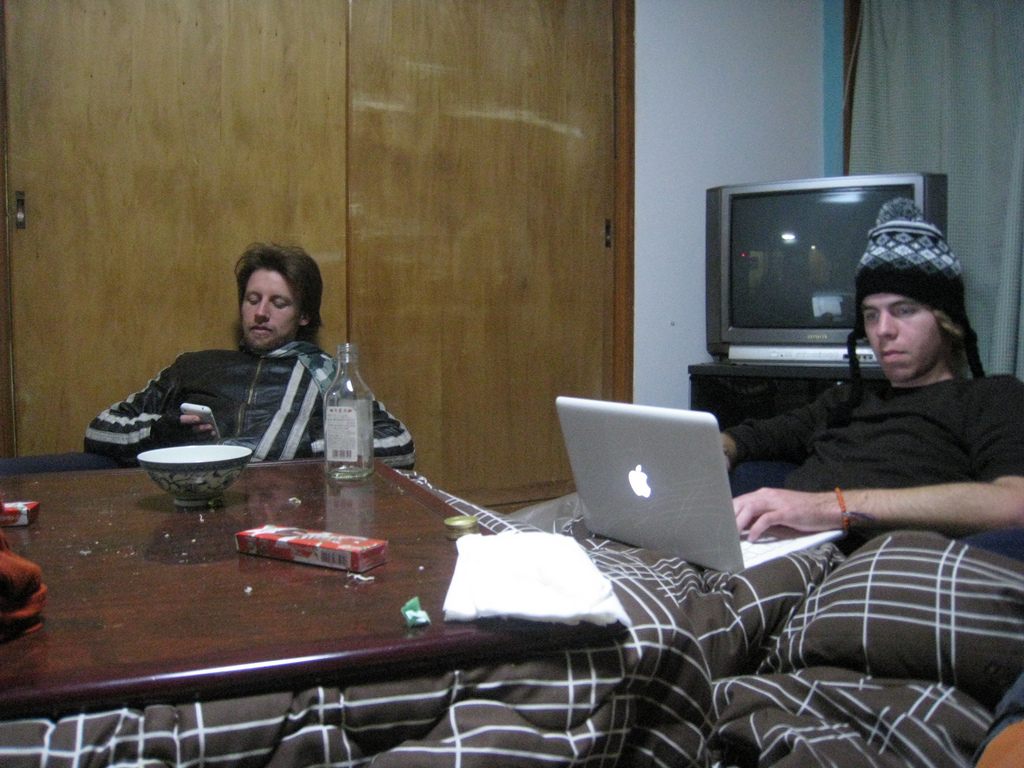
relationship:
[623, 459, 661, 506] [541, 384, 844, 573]
apple on computer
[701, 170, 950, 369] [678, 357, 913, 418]
television set on table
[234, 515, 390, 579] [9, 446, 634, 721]
cigarette box on table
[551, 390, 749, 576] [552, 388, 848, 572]
back lid on laptop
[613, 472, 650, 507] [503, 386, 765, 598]
back lid of laptop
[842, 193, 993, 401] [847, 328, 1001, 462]
bonnet hat on man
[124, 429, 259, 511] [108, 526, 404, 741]
bowl bowl on table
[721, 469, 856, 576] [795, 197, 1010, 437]
hand of man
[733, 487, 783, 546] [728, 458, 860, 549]
finger on hand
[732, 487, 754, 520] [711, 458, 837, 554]
finger on hand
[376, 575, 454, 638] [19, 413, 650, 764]
garbage on table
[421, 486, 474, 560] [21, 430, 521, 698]
garbage on wood table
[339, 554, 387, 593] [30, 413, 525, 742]
garbage on wood table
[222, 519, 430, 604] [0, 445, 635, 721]
garbage on table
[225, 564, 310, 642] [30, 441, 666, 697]
garbage on wood table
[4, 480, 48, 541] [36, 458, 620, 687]
garbage on wood table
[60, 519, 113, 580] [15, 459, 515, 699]
garbage on wood table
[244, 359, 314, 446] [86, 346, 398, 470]
stripes on a jacket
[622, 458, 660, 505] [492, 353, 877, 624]
apple on a laptop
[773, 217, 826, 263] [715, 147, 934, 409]
reflection on a tv screen